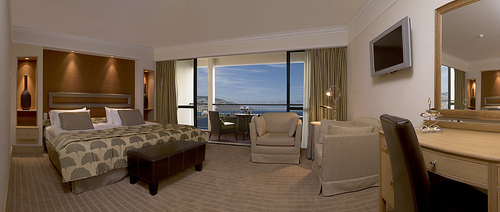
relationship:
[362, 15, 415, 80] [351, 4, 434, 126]
television on wall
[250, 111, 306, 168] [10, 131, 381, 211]
chair on floor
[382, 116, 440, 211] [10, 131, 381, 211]
chair on floor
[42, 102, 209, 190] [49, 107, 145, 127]
bed has pillows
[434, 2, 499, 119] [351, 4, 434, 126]
mirror on wall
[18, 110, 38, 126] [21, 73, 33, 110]
shelf has vase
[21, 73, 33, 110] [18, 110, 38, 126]
vase on shelf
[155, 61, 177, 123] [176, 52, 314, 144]
curtains on window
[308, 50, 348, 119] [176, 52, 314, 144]
curtains on window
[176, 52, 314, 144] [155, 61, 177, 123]
window has curtains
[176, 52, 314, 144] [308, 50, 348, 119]
window has curtains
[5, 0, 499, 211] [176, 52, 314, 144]
room has window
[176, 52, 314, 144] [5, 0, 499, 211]
window in room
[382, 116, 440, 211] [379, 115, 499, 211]
chair near desk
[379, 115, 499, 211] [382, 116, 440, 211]
desk near chair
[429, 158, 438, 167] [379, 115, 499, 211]
handle on desk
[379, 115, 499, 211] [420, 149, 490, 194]
desk has drawer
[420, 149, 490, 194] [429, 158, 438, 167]
drawer has handle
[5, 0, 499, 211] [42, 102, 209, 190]
room has bed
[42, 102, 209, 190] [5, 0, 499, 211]
bed in room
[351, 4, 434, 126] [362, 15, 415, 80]
wall has television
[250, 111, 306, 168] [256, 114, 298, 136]
chair has pillows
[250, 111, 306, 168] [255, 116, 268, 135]
chair has pillow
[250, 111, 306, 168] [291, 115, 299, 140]
chair has pillow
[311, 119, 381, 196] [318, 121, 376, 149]
couch has pillows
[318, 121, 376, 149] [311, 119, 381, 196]
pillows on couch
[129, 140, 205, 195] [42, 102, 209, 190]
bench near bed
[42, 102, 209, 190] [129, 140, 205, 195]
bed near bench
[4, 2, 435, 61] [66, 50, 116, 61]
ceiling has lights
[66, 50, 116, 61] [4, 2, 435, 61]
lights in ceiling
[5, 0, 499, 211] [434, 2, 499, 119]
room in mirror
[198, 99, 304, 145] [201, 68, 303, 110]
balcony has view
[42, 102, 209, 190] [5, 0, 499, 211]
bed in bedroom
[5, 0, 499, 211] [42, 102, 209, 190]
bedroom has bed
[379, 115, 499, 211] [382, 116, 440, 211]
desk has chair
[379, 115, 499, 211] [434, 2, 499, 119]
desk has mirror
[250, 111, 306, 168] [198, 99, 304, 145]
chair near balcony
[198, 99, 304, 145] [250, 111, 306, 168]
balcony near chair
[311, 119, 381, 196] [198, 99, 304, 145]
couch near balcony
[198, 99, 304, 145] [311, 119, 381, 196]
balcony near couch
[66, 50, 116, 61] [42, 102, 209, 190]
lights above bed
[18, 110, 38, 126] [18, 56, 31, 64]
shelf has light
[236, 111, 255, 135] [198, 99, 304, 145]
table on balcony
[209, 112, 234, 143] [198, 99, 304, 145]
chair on balcony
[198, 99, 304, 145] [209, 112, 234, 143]
balcony has chair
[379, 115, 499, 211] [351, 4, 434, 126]
desk against wall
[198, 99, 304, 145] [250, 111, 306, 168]
balcony behind chair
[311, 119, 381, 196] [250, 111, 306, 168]
couch next to chair